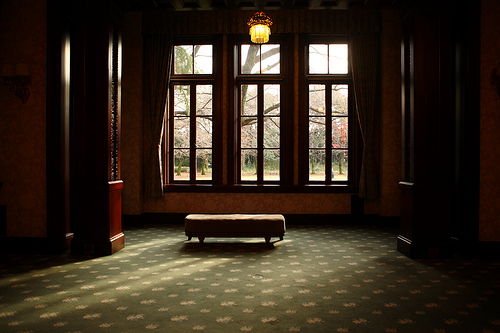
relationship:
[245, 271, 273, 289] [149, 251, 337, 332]
part of floor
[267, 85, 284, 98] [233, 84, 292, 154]
part of window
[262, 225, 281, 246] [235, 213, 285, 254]
part of stand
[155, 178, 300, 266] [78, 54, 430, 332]
bench in room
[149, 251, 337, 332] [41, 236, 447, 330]
floor with carpet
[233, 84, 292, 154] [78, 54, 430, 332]
window in room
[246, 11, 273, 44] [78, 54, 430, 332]
light in room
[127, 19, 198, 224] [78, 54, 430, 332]
curtain in room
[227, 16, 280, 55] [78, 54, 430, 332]
light in room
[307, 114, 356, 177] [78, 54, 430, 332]
tree in background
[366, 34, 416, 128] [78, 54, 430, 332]
wall in room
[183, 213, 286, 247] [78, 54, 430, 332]
bench in room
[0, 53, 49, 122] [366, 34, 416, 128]
lamp on wall